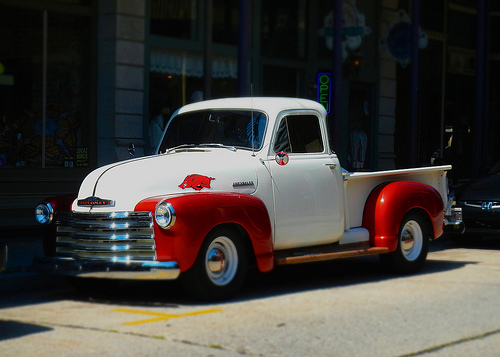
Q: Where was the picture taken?
A: It was taken at the pavement.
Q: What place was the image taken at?
A: It was taken at the pavement.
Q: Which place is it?
A: It is a pavement.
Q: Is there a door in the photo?
A: Yes, there is a door.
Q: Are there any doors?
A: Yes, there is a door.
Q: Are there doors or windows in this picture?
A: Yes, there is a door.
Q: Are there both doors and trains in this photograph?
A: No, there is a door but no trains.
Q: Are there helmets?
A: No, there are no helmets.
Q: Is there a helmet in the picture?
A: No, there are no helmets.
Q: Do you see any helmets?
A: No, there are no helmets.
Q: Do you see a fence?
A: No, there are no fences.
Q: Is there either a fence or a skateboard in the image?
A: No, there are no fences or skateboards.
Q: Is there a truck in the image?
A: Yes, there is a truck.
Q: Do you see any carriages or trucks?
A: Yes, there is a truck.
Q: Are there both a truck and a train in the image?
A: No, there is a truck but no trains.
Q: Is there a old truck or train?
A: Yes, there is an old truck.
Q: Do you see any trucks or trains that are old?
A: Yes, the truck is old.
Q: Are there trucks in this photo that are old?
A: Yes, there is an old truck.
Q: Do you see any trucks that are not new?
A: Yes, there is a old truck.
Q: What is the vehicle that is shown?
A: The vehicle is a truck.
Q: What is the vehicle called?
A: The vehicle is a truck.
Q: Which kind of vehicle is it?
A: The vehicle is a truck.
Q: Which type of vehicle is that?
A: This is a truck.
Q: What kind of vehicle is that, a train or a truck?
A: This is a truck.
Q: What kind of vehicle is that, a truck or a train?
A: This is a truck.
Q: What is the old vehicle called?
A: The vehicle is a truck.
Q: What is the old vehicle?
A: The vehicle is a truck.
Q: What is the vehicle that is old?
A: The vehicle is a truck.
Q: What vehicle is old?
A: The vehicle is a truck.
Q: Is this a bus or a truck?
A: This is a truck.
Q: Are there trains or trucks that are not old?
A: No, there is a truck but it is old.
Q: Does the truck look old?
A: Yes, the truck is old.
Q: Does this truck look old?
A: Yes, the truck is old.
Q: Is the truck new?
A: No, the truck is old.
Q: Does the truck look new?
A: No, the truck is old.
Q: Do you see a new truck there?
A: No, there is a truck but it is old.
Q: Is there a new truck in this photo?
A: No, there is a truck but it is old.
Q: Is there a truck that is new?
A: No, there is a truck but it is old.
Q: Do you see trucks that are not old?
A: No, there is a truck but it is old.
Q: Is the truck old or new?
A: The truck is old.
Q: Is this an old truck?
A: Yes, this is an old truck.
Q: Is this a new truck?
A: No, this is an old truck.